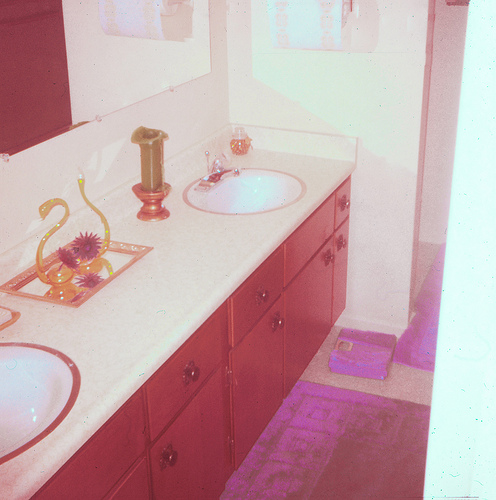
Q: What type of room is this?
A: Bathroom.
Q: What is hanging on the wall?
A: Paper towels.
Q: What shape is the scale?
A: Square.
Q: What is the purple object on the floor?
A: Rug.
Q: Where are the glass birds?
A: Mirrored tray.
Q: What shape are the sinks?
A: Round.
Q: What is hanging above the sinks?
A: Mirror.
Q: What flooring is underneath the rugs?
A: Linoleum.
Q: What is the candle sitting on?
A: Wooden base.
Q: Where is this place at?
A: Bathroom.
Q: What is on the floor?
A: A rug.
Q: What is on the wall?
A: Mirror.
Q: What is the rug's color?
A: Purple.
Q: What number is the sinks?
A: 2.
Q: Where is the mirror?
A: On the wall above the sinks.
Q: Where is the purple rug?
A: On the floor.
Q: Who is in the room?
A: No one.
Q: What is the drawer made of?
A: Wood.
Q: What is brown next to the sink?
A: Candle.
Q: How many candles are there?
A: 1.